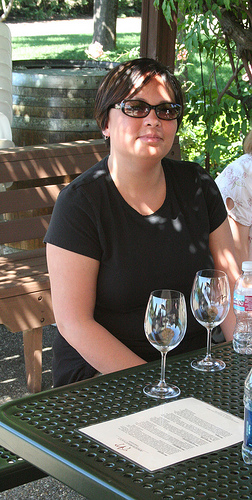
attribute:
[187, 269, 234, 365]
wine glass — clear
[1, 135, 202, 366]
bench — brown, wooden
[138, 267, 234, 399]
glasses — clear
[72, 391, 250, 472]
paper — white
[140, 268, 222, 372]
glasses — empty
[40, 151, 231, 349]
shirt — black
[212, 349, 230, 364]
table — green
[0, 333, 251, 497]
table — green, plastic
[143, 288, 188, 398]
glasses — empty, for wine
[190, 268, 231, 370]
glasses — empty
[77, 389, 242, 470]
paper — white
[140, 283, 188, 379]
wine glass — clear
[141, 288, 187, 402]
glass — empty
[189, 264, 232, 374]
glass — empty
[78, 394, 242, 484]
paper — white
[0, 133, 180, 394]
bench — brown, wooden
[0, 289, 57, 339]
bench — brown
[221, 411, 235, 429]
paper — white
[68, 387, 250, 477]
paper — white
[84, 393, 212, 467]
paper — white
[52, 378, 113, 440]
table — green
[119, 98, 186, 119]
sunglasses — black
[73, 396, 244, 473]
paper — white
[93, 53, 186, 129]
hair — dark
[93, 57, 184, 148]
hair — short